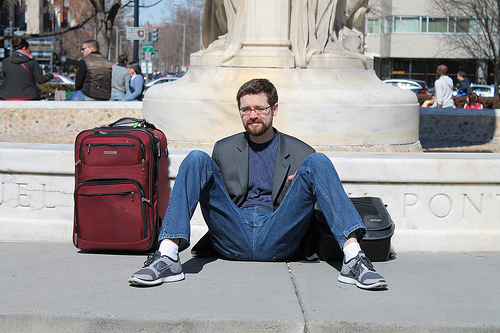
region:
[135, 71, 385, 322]
A man sitting on the sidewalk.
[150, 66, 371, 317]
A man wearing blue jeans.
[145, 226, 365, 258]
A pair of white socks.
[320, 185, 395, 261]
Small black suitcase beside of man.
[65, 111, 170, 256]
Large red suitcase beside of man.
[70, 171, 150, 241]
Large storage compartment on front of red suitcase.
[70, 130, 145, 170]
Small storage compartment on front of red suitcase.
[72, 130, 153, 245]
Zippers on front of red suitcase.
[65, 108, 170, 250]
this is a case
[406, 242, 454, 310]
this is a grey road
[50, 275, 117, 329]
this is a grey road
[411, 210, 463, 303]
this is a grey road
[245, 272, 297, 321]
this is a grey road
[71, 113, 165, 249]
a piece of red luggage on the floor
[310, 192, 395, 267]
a piece of black luggage on the floor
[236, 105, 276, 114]
a man with glasses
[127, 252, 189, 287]
a man with grey shoes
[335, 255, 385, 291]
a man with grey shoes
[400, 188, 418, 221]
the letter P in marble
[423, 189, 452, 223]
the letter O in marble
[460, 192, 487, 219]
the letter N in marble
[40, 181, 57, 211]
the letter L in marble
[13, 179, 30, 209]
the letter E in marble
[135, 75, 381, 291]
a man sitting on the ground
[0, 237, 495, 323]
the sidewalk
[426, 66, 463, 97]
people walking on the street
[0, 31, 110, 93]
people sitting on a wall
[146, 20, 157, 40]
a street light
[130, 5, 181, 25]
the sky behind the trees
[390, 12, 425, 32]
a window on the building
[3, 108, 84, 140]
rocks on the wall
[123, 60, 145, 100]
a woman in a blue shirt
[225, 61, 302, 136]
head of a person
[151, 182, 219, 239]
leg of a person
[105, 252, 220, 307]
feet of a person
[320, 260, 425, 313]
feet of a person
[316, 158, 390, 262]
leg of a person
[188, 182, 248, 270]
thigh of a person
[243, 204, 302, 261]
croch of a person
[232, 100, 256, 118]
eye of a person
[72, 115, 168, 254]
luggage sitting next to man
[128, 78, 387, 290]
man sitting on sidewalk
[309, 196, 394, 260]
luggage sitting next to sidewalk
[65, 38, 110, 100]
person sitting near statue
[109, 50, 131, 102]
person standing near statue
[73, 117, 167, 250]
red bag nex to man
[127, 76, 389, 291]
man sitting in the floor wearing blue jeans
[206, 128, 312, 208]
man wearing gray jacket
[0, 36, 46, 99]
woman sitting wearing black sweater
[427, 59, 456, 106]
person wearing white jacket in the background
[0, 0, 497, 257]
concrete font behind man sitting in sidewalk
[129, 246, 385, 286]
black and white shoes that man is wearing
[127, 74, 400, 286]
man sitting in the sidewalk wearing glasses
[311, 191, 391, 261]
black bag next to man sitting in sidewalk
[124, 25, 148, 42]
black and whtie signpost in the background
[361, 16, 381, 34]
a window on a building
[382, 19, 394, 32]
a window on a building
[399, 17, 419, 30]
a window on a building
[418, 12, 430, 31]
a window on a building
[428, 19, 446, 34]
a window on a building